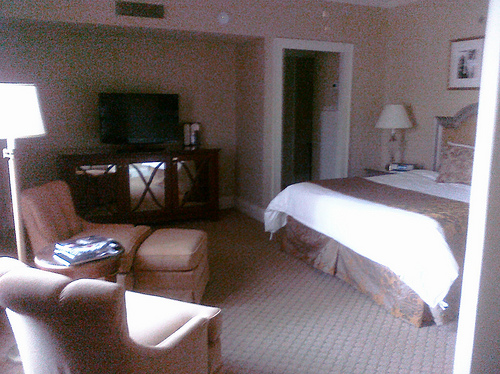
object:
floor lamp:
[0, 82, 47, 264]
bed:
[263, 103, 478, 329]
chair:
[18, 179, 212, 305]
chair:
[0, 255, 225, 374]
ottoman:
[132, 228, 212, 304]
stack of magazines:
[52, 234, 125, 266]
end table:
[33, 236, 126, 283]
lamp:
[373, 103, 414, 171]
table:
[363, 165, 422, 177]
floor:
[0, 206, 460, 374]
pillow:
[435, 140, 475, 186]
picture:
[446, 36, 485, 91]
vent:
[114, 1, 166, 19]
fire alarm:
[217, 11, 229, 24]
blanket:
[264, 180, 459, 311]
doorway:
[267, 37, 355, 203]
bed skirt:
[276, 215, 434, 328]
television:
[97, 91, 181, 154]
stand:
[55, 144, 221, 224]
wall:
[376, 6, 488, 170]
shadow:
[200, 238, 257, 306]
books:
[183, 122, 200, 146]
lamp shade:
[374, 104, 415, 129]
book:
[388, 161, 414, 172]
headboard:
[432, 102, 479, 171]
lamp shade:
[0, 82, 47, 140]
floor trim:
[218, 192, 266, 226]